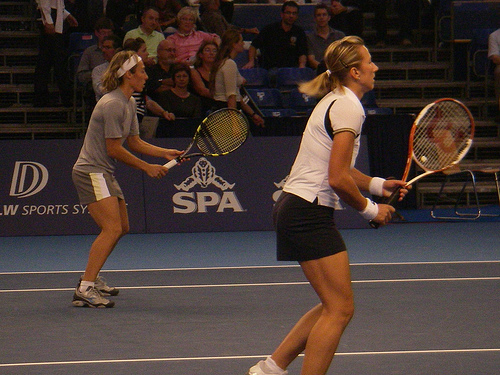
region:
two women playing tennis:
[5, 8, 492, 368]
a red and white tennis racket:
[384, 87, 477, 196]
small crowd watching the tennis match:
[68, 12, 305, 128]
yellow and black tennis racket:
[180, 115, 252, 156]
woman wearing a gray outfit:
[85, 53, 150, 275]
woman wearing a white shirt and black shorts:
[294, 35, 382, 282]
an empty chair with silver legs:
[427, 124, 499, 228]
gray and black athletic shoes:
[69, 272, 121, 311]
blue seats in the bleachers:
[240, 67, 292, 126]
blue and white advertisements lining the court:
[3, 152, 290, 231]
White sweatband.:
[106, 49, 151, 81]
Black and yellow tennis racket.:
[154, 103, 256, 190]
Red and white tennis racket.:
[351, 96, 488, 233]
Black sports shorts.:
[265, 184, 359, 268]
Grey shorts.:
[65, 164, 134, 209]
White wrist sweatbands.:
[357, 170, 390, 231]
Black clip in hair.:
[335, 48, 353, 71]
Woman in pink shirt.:
[156, 4, 228, 69]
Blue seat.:
[244, 84, 292, 124]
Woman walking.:
[200, 30, 269, 146]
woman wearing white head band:
[73, 37, 172, 305]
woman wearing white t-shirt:
[255, 21, 415, 373]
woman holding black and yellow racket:
[71, 42, 261, 372]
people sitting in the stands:
[142, 13, 239, 122]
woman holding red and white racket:
[258, 28, 472, 363]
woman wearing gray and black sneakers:
[56, 54, 159, 332]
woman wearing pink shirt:
[163, 10, 222, 68]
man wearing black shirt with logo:
[253, 2, 308, 72]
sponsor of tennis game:
[176, 142, 251, 243]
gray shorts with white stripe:
[71, 152, 125, 216]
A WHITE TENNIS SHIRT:
[286, 94, 370, 212]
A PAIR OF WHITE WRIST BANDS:
[353, 147, 388, 232]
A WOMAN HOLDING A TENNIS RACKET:
[62, 44, 254, 312]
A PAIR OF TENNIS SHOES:
[56, 268, 130, 314]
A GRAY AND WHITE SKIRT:
[71, 162, 147, 209]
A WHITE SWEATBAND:
[108, 49, 147, 81]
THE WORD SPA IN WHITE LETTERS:
[164, 185, 259, 221]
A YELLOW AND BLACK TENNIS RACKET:
[160, 102, 255, 178]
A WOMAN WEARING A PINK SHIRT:
[162, 2, 232, 61]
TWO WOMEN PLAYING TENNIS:
[57, 30, 479, 360]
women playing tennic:
[53, 40, 473, 357]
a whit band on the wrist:
[359, 187, 383, 225]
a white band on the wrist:
[369, 184, 384, 196]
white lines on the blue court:
[181, 262, 253, 293]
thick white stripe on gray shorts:
[84, 174, 118, 199]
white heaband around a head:
[115, 60, 143, 70]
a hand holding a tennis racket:
[380, 175, 420, 202]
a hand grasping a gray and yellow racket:
[149, 157, 166, 177]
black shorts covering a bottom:
[272, 187, 346, 263]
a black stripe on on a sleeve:
[323, 93, 336, 132]